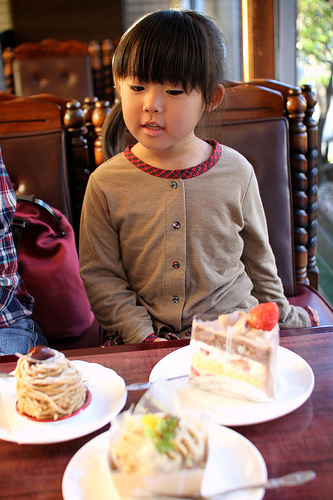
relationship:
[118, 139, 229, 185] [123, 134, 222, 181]
trim on collar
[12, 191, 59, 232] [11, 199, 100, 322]
handle on bag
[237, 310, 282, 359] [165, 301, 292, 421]
wax paper wrapped on cake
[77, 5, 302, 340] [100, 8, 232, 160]
girl has hair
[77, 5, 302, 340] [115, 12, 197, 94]
girl has bangs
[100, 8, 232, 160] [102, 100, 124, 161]
hair has ponytail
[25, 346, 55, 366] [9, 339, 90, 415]
plum in noodle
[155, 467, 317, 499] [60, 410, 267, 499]
fork on plant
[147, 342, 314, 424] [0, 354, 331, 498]
plate on table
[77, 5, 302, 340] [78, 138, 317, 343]
girl wearing shirt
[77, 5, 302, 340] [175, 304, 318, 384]
girl looking at cake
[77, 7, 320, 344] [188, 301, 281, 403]
girl looking at cake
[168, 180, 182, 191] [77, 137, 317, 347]
button on shirt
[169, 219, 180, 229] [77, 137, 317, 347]
button on shirt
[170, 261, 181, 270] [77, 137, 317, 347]
button on shirt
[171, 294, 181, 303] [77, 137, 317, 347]
button on shirt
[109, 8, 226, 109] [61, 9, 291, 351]
hair on girl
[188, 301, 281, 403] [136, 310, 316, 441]
cake on plate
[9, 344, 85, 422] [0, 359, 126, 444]
cake on plate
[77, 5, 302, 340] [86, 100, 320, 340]
girl on chair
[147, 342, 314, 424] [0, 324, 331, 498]
plate on table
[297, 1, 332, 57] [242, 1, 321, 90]
tree by door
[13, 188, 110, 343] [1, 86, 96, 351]
bag sitting on chair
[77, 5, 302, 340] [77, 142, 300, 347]
girl wearing shirt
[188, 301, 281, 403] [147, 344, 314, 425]
cake served on plate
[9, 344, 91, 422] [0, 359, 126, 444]
cake served on plate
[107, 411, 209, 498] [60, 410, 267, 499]
cake served on plant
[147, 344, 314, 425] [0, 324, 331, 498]
plate sitting on table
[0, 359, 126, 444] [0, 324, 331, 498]
plate sitting on table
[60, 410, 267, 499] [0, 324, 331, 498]
plant sitting on table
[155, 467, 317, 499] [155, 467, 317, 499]
fork part of fork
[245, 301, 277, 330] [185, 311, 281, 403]
strawberry part of cake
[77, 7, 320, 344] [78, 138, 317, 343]
girl wearing shirt